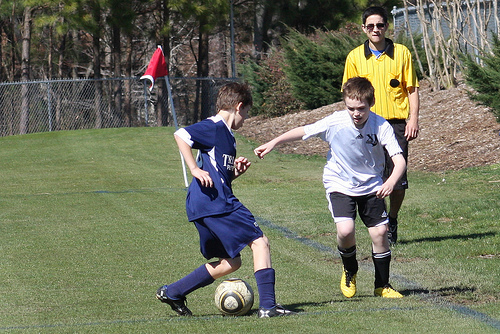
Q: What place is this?
A: It is a field.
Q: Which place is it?
A: It is a field.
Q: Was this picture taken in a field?
A: Yes, it was taken in a field.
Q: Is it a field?
A: Yes, it is a field.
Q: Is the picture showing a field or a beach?
A: It is showing a field.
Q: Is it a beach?
A: No, it is a field.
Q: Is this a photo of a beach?
A: No, the picture is showing a field.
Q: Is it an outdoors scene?
A: Yes, it is outdoors.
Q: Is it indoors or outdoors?
A: It is outdoors.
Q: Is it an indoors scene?
A: No, it is outdoors.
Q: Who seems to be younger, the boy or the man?
A: The boy is younger than the man.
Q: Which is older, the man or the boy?
A: The man is older than the boy.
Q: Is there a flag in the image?
A: Yes, there is a flag.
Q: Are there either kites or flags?
A: Yes, there is a flag.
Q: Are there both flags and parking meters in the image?
A: No, there is a flag but no parking meters.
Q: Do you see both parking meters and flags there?
A: No, there is a flag but no parking meters.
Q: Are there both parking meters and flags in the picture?
A: No, there is a flag but no parking meters.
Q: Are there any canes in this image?
A: No, there are no canes.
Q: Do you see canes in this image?
A: No, there are no canes.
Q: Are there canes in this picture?
A: No, there are no canes.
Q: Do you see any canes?
A: No, there are no canes.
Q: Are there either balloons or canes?
A: No, there are no canes or balloons.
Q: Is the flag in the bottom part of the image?
A: No, the flag is in the top of the image.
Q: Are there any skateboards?
A: No, there are no skateboards.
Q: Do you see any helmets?
A: No, there are no helmets.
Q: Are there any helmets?
A: No, there are no helmets.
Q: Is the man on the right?
A: Yes, the man is on the right of the image.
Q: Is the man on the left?
A: No, the man is on the right of the image.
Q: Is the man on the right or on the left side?
A: The man is on the right of the image.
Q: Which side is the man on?
A: The man is on the right of the image.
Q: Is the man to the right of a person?
A: Yes, the man is to the right of a person.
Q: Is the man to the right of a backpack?
A: No, the man is to the right of a person.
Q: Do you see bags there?
A: No, there are no bags.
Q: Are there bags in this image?
A: No, there are no bags.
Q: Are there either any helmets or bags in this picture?
A: No, there are no bags or helmets.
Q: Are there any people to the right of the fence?
A: Yes, there is a person to the right of the fence.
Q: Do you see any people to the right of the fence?
A: Yes, there is a person to the right of the fence.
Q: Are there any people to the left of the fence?
A: No, the person is to the right of the fence.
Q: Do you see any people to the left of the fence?
A: No, the person is to the right of the fence.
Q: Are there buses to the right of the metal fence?
A: No, there is a person to the right of the fence.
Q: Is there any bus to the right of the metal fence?
A: No, there is a person to the right of the fence.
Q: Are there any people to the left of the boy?
A: Yes, there is a person to the left of the boy.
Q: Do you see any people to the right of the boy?
A: No, the person is to the left of the boy.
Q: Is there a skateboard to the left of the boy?
A: No, there is a person to the left of the boy.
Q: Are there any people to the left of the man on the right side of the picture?
A: Yes, there is a person to the left of the man.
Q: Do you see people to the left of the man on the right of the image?
A: Yes, there is a person to the left of the man.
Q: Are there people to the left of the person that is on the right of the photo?
A: Yes, there is a person to the left of the man.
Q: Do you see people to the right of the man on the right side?
A: No, the person is to the left of the man.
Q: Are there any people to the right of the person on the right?
A: No, the person is to the left of the man.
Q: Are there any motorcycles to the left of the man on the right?
A: No, there is a person to the left of the man.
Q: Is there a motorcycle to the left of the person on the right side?
A: No, there is a person to the left of the man.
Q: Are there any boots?
A: Yes, there are boots.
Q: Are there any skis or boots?
A: Yes, there are boots.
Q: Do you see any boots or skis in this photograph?
A: Yes, there are boots.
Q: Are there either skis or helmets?
A: No, there are no helmets or skis.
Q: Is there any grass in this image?
A: Yes, there is grass.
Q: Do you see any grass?
A: Yes, there is grass.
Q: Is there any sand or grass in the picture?
A: Yes, there is grass.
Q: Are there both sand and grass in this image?
A: No, there is grass but no sand.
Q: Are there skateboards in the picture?
A: No, there are no skateboards.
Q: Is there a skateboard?
A: No, there are no skateboards.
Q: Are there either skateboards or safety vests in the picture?
A: No, there are no skateboards or safety vests.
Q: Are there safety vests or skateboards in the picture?
A: No, there are no skateboards or safety vests.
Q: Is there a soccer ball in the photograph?
A: Yes, there is a soccer ball.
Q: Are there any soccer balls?
A: Yes, there is a soccer ball.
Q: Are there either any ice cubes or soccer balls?
A: Yes, there is a soccer ball.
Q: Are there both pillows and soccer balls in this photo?
A: No, there is a soccer ball but no pillows.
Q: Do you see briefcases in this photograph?
A: No, there are no briefcases.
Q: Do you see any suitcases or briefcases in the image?
A: No, there are no briefcases or suitcases.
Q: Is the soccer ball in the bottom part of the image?
A: Yes, the soccer ball is in the bottom of the image.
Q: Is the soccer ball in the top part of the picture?
A: No, the soccer ball is in the bottom of the image.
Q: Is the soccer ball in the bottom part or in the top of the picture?
A: The soccer ball is in the bottom of the image.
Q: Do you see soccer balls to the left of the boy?
A: Yes, there is a soccer ball to the left of the boy.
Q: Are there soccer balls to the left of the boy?
A: Yes, there is a soccer ball to the left of the boy.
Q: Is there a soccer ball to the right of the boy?
A: No, the soccer ball is to the left of the boy.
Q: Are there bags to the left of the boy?
A: No, there is a soccer ball to the left of the boy.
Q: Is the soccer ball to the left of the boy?
A: Yes, the soccer ball is to the left of the boy.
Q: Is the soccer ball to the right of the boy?
A: No, the soccer ball is to the left of the boy.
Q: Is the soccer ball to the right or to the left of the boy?
A: The soccer ball is to the left of the boy.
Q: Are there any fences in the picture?
A: Yes, there is a fence.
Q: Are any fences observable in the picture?
A: Yes, there is a fence.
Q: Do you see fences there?
A: Yes, there is a fence.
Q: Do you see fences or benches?
A: Yes, there is a fence.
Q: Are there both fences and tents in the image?
A: No, there is a fence but no tents.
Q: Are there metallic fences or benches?
A: Yes, there is a metal fence.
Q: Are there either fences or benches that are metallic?
A: Yes, the fence is metallic.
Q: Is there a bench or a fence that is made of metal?
A: Yes, the fence is made of metal.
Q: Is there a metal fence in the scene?
A: Yes, there is a metal fence.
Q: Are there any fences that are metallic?
A: Yes, there is a fence that is metallic.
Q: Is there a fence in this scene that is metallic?
A: Yes, there is a fence that is metallic.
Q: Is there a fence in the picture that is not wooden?
A: Yes, there is a metallic fence.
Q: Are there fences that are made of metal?
A: Yes, there is a fence that is made of metal.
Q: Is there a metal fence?
A: Yes, there is a fence that is made of metal.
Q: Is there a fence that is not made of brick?
A: Yes, there is a fence that is made of metal.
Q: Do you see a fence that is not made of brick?
A: Yes, there is a fence that is made of metal.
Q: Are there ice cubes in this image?
A: No, there are no ice cubes.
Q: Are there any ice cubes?
A: No, there are no ice cubes.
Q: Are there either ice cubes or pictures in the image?
A: No, there are no ice cubes or pictures.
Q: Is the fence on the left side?
A: Yes, the fence is on the left of the image.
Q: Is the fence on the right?
A: No, the fence is on the left of the image.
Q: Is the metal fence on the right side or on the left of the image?
A: The fence is on the left of the image.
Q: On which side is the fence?
A: The fence is on the left of the image.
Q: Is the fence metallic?
A: Yes, the fence is metallic.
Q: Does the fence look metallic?
A: Yes, the fence is metallic.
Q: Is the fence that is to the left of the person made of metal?
A: Yes, the fence is made of metal.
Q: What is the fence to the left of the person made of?
A: The fence is made of metal.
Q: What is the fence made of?
A: The fence is made of metal.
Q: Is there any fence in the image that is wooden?
A: No, there is a fence but it is metallic.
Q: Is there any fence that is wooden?
A: No, there is a fence but it is metallic.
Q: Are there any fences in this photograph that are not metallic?
A: No, there is a fence but it is metallic.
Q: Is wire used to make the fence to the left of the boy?
A: No, the fence is made of metal.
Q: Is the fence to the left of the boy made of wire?
A: No, the fence is made of metal.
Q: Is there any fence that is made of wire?
A: No, there is a fence but it is made of metal.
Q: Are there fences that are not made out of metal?
A: No, there is a fence but it is made of metal.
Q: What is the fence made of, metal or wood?
A: The fence is made of metal.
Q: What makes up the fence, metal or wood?
A: The fence is made of metal.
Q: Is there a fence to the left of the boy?
A: Yes, there is a fence to the left of the boy.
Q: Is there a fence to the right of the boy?
A: No, the fence is to the left of the boy.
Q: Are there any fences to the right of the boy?
A: No, the fence is to the left of the boy.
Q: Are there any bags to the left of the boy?
A: No, there is a fence to the left of the boy.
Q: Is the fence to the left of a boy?
A: Yes, the fence is to the left of a boy.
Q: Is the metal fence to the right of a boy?
A: No, the fence is to the left of a boy.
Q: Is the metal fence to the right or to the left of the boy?
A: The fence is to the left of the boy.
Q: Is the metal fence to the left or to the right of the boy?
A: The fence is to the left of the boy.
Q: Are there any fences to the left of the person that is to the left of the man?
A: Yes, there is a fence to the left of the person.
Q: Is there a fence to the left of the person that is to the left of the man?
A: Yes, there is a fence to the left of the person.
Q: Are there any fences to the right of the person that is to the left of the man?
A: No, the fence is to the left of the person.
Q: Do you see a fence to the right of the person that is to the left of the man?
A: No, the fence is to the left of the person.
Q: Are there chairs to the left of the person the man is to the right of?
A: No, there is a fence to the left of the person.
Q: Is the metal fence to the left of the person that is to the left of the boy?
A: Yes, the fence is to the left of the person.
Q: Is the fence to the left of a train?
A: No, the fence is to the left of the person.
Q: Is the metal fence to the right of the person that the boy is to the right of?
A: No, the fence is to the left of the person.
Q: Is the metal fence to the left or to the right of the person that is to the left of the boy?
A: The fence is to the left of the person.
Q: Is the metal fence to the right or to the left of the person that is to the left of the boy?
A: The fence is to the left of the person.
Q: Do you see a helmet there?
A: No, there are no helmets.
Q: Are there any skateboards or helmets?
A: No, there are no helmets or skateboards.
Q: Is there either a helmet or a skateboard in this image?
A: No, there are no helmets or skateboards.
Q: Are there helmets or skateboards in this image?
A: No, there are no helmets or skateboards.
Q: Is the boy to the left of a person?
A: No, the boy is to the right of a person.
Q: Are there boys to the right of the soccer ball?
A: Yes, there is a boy to the right of the soccer ball.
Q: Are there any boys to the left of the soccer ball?
A: No, the boy is to the right of the soccer ball.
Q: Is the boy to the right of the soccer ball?
A: Yes, the boy is to the right of the soccer ball.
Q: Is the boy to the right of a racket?
A: No, the boy is to the right of the soccer ball.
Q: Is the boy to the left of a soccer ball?
A: No, the boy is to the right of a soccer ball.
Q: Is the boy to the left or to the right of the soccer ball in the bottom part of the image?
A: The boy is to the right of the soccer ball.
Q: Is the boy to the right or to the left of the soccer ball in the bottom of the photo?
A: The boy is to the right of the soccer ball.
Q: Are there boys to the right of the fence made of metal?
A: Yes, there is a boy to the right of the fence.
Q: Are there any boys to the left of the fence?
A: No, the boy is to the right of the fence.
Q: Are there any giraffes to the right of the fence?
A: No, there is a boy to the right of the fence.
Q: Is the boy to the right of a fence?
A: Yes, the boy is to the right of a fence.